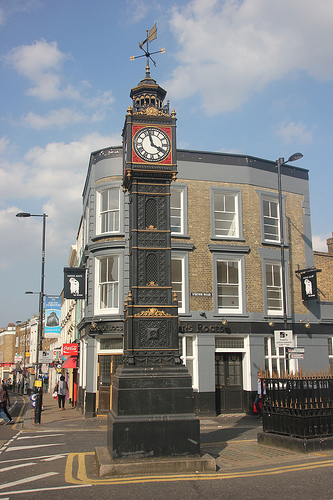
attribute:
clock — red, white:
[130, 120, 175, 169]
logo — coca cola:
[61, 342, 80, 356]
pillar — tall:
[95, 66, 220, 478]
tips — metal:
[256, 368, 332, 379]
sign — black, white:
[274, 329, 297, 352]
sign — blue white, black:
[44, 294, 65, 339]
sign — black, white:
[62, 265, 88, 301]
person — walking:
[52, 374, 72, 412]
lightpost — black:
[37, 212, 47, 396]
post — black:
[38, 214, 48, 402]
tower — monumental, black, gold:
[95, 75, 220, 477]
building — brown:
[78, 144, 332, 415]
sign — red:
[61, 342, 80, 358]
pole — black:
[35, 212, 51, 382]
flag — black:
[64, 265, 85, 299]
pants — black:
[55, 391, 67, 410]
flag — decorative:
[44, 294, 61, 339]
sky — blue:
[2, 1, 332, 324]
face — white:
[134, 129, 168, 163]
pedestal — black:
[92, 443, 219, 475]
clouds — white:
[2, 2, 332, 267]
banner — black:
[297, 268, 322, 304]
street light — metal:
[16, 211, 48, 403]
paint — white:
[2, 431, 65, 500]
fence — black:
[259, 369, 332, 445]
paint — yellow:
[64, 447, 332, 490]